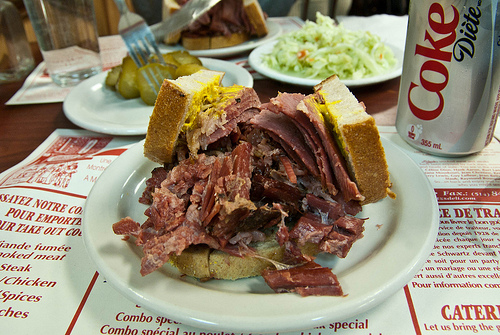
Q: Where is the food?
A: On the white plate.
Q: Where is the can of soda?
A: Near the food.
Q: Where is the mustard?
A: On the brad.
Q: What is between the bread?
A: Meat.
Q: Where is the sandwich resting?
A: On the plate.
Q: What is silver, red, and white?
A: The can.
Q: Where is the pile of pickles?
A: On a plate.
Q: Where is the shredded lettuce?
A: On the plate.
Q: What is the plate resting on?
A: A white mat.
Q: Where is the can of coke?
A: On the table.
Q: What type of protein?
A: Meat.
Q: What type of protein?
A: Meat.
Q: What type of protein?
A: Meat.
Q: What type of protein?
A: Meat.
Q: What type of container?
A: Can.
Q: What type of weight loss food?
A: Salad.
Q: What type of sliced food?
A: Pickles.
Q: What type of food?
A: Sandwich.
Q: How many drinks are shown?
A: Two.